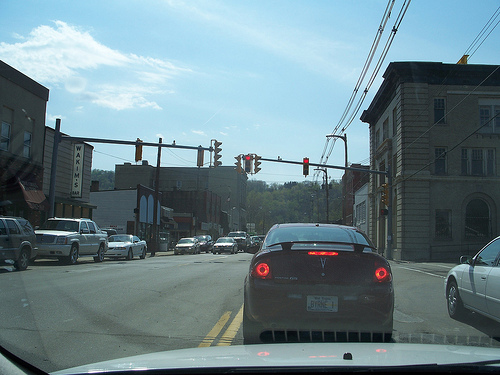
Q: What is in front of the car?
A: Another car.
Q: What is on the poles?
A: Traffic lights.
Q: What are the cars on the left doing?
A: Parked.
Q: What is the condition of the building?
A: Old.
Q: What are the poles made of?
A: Metal.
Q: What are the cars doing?
A: Waiting at the light.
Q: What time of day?
A: In the afternoon.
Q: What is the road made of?
A: Asphalt.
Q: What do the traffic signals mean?
A: To stop.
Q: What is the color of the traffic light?
A: Red.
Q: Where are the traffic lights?
A: At the center of the street.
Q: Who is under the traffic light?
A: No one.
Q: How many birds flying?
A: Zero.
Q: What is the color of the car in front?
A: Black.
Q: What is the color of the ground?
A: Gray.